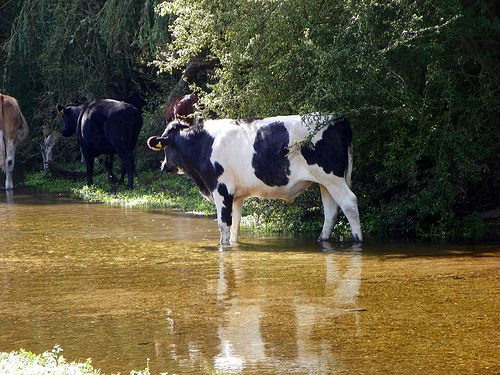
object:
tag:
[153, 139, 164, 148]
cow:
[148, 109, 364, 248]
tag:
[59, 108, 65, 114]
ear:
[55, 104, 65, 115]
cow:
[38, 88, 63, 175]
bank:
[18, 158, 317, 235]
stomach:
[239, 173, 275, 192]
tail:
[343, 146, 354, 189]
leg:
[213, 177, 234, 250]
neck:
[170, 123, 199, 175]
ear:
[146, 136, 169, 152]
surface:
[84, 286, 428, 366]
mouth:
[158, 158, 184, 174]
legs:
[330, 184, 366, 243]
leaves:
[241, 35, 276, 65]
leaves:
[305, 72, 341, 104]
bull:
[0, 91, 29, 195]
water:
[12, 206, 419, 373]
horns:
[169, 121, 179, 128]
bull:
[52, 95, 144, 191]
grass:
[138, 176, 165, 203]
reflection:
[201, 287, 333, 371]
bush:
[316, 11, 500, 107]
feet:
[85, 179, 97, 186]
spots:
[249, 119, 299, 187]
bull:
[163, 90, 204, 125]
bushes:
[0, 27, 77, 101]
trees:
[358, 0, 500, 170]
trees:
[0, 0, 172, 103]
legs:
[226, 195, 246, 248]